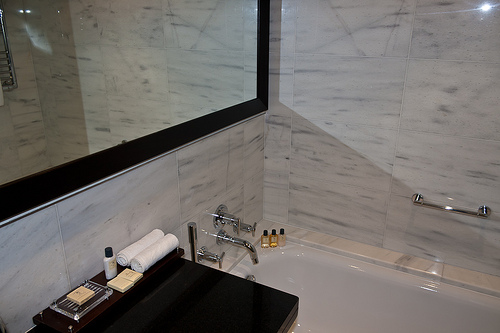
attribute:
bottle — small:
[276, 227, 290, 249]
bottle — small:
[267, 227, 277, 246]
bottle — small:
[260, 227, 269, 249]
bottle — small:
[267, 223, 277, 245]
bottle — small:
[269, 228, 278, 247]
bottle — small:
[260, 229, 270, 247]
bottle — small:
[102, 245, 118, 279]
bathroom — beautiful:
[6, 16, 498, 326]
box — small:
[58, 256, 129, 320]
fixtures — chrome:
[207, 197, 272, 270]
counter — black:
[58, 249, 307, 321]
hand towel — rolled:
[131, 231, 196, 279]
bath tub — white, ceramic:
[224, 221, 498, 326]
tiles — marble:
[280, 12, 463, 187]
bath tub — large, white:
[150, 162, 418, 331]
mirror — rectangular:
[0, 5, 299, 213]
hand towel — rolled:
[119, 231, 160, 264]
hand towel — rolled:
[129, 234, 178, 269]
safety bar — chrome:
[410, 190, 492, 222]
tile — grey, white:
[285, 116, 397, 231]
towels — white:
[128, 232, 180, 277]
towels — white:
[112, 227, 165, 269]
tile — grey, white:
[283, 5, 415, 62]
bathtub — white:
[229, 235, 498, 332]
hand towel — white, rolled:
[142, 232, 174, 287]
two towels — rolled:
[96, 221, 221, 277]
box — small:
[88, 251, 188, 321]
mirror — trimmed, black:
[2, 5, 287, 180]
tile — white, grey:
[189, 141, 265, 211]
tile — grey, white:
[127, 163, 185, 231]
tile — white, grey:
[396, 90, 498, 192]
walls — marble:
[286, 2, 499, 201]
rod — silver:
[393, 177, 484, 224]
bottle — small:
[261, 228, 270, 246]